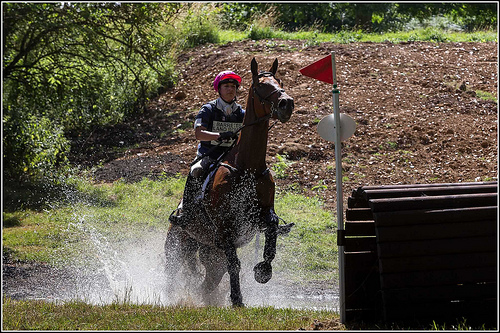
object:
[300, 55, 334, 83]
flag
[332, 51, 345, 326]
pole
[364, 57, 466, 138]
dirt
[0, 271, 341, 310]
creek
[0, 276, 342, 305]
water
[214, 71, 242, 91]
helmet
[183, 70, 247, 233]
jockey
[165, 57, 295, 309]
horse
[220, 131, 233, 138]
glove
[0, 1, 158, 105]
tree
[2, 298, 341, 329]
grass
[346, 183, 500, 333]
structure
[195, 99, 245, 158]
uniform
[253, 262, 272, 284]
hoof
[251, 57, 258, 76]
ear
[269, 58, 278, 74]
ear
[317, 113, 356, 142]
sign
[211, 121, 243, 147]
sign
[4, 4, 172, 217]
woods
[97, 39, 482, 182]
hill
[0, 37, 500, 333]
ground